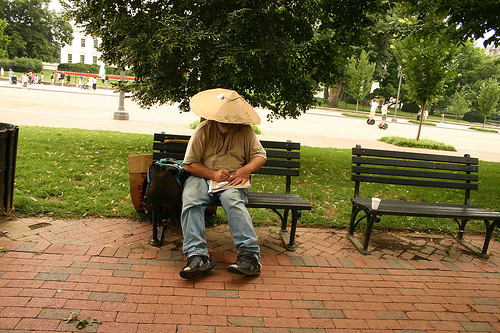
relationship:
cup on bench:
[370, 195, 380, 212] [335, 138, 499, 259]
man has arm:
[177, 89, 267, 286] [187, 160, 220, 182]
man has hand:
[177, 89, 267, 286] [214, 168, 229, 180]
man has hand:
[177, 89, 267, 286] [223, 143, 278, 189]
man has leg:
[177, 89, 267, 286] [219, 185, 261, 275]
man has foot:
[177, 89, 267, 286] [226, 255, 261, 278]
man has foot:
[177, 89, 267, 286] [179, 253, 215, 281]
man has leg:
[177, 89, 267, 286] [220, 188, 267, 275]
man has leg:
[177, 89, 267, 286] [179, 176, 209, 279]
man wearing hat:
[177, 89, 267, 286] [189, 87, 254, 122]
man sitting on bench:
[177, 89, 267, 286] [145, 129, 312, 256]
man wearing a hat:
[177, 89, 267, 286] [190, 88, 265, 125]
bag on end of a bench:
[112, 143, 167, 210] [112, 119, 353, 241]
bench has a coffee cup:
[335, 138, 499, 259] [369, 198, 385, 208]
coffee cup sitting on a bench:
[369, 198, 385, 208] [335, 138, 499, 259]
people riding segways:
[381, 98, 387, 125] [366, 114, 388, 130]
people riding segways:
[371, 100, 378, 125] [366, 114, 388, 130]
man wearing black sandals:
[193, 60, 250, 255] [184, 249, 260, 279]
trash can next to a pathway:
[2, 117, 37, 213] [18, 199, 465, 319]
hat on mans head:
[188, 87, 261, 123] [215, 121, 233, 134]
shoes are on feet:
[183, 247, 261, 282] [227, 256, 262, 278]